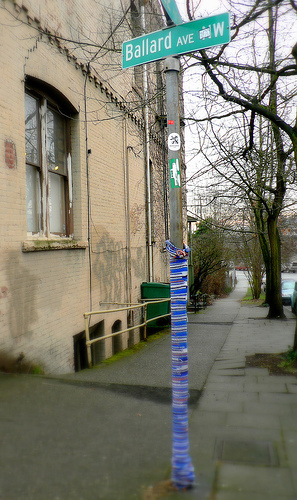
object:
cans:
[138, 280, 171, 330]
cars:
[259, 270, 295, 316]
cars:
[229, 260, 296, 272]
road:
[226, 269, 296, 311]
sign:
[121, 11, 230, 68]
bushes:
[191, 215, 231, 296]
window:
[24, 84, 75, 239]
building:
[0, 0, 188, 377]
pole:
[164, 56, 196, 487]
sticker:
[167, 132, 181, 151]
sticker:
[168, 119, 174, 124]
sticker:
[169, 158, 180, 188]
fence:
[81, 297, 171, 368]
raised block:
[213, 361, 246, 368]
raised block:
[212, 353, 239, 361]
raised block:
[210, 366, 245, 375]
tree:
[232, 202, 263, 300]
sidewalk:
[0, 271, 297, 451]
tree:
[179, 0, 297, 320]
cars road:
[233, 259, 249, 278]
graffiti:
[93, 229, 130, 310]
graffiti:
[5, 254, 39, 347]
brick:
[93, 108, 123, 230]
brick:
[1, 20, 20, 134]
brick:
[2, 176, 21, 245]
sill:
[23, 236, 89, 250]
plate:
[212, 434, 281, 465]